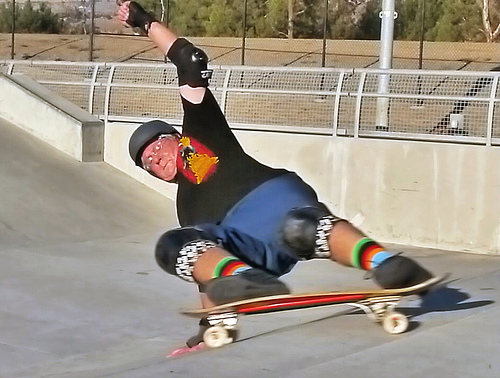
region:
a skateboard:
[289, 285, 356, 302]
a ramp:
[59, 276, 128, 333]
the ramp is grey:
[24, 228, 87, 304]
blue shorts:
[243, 194, 280, 236]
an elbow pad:
[177, 46, 210, 87]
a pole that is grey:
[378, 14, 398, 63]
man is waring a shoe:
[208, 272, 266, 297]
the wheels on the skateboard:
[382, 316, 407, 331]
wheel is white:
[201, 322, 226, 345]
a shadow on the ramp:
[424, 287, 454, 313]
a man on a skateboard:
[108, 49, 418, 364]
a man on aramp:
[144, 81, 496, 374]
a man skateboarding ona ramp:
[83, 96, 493, 371]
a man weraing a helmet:
[99, 65, 411, 370]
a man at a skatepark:
[144, 39, 450, 364]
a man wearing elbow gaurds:
[72, 4, 384, 354]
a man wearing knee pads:
[114, 147, 479, 372]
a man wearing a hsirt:
[100, 85, 330, 275]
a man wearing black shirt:
[72, 89, 339, 264]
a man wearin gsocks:
[230, 138, 486, 295]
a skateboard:
[177, 271, 446, 346]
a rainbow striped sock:
[348, 235, 388, 265]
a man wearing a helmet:
[127, 118, 180, 180]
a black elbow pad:
[165, 37, 210, 87]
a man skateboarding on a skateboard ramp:
[0, 0, 494, 369]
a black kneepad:
[281, 203, 320, 255]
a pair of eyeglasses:
[139, 134, 169, 171]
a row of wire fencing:
[3, 65, 492, 141]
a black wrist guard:
[118, 1, 155, 34]